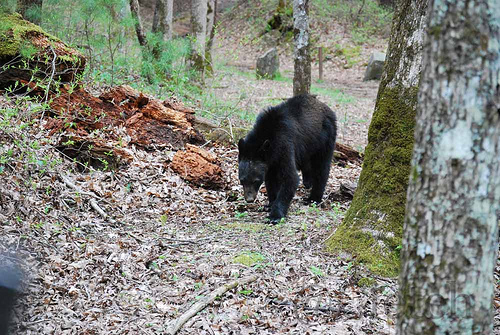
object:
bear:
[235, 95, 342, 222]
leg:
[308, 164, 331, 204]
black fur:
[319, 173, 323, 182]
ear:
[259, 140, 276, 154]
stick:
[159, 270, 260, 334]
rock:
[365, 50, 379, 79]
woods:
[6, 25, 45, 72]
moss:
[322, 78, 421, 277]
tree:
[9, 0, 66, 104]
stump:
[253, 42, 280, 77]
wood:
[176, 145, 221, 185]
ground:
[119, 225, 200, 285]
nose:
[245, 192, 258, 204]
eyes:
[239, 173, 251, 189]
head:
[234, 158, 271, 203]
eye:
[254, 178, 260, 188]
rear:
[308, 109, 337, 147]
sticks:
[53, 153, 121, 232]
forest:
[28, 11, 214, 188]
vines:
[79, 3, 138, 48]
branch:
[38, 47, 59, 128]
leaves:
[188, 244, 219, 275]